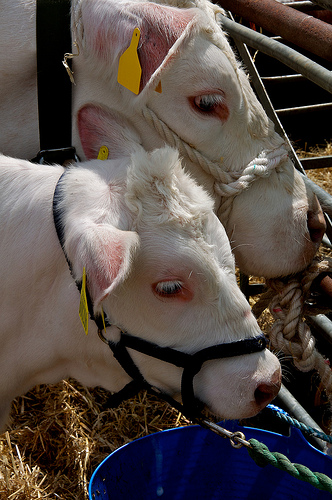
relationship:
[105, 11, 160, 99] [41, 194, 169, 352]
tag in ear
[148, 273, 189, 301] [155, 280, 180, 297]
pink circle around eye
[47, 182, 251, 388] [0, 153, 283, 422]
straps around head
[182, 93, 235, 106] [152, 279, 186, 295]
eyelashes on eye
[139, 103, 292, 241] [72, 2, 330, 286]
rope around head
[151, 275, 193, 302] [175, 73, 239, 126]
ring around eye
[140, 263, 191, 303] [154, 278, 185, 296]
eyelashes on eye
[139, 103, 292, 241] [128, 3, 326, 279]
rope around face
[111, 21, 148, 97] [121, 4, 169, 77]
yelllow tag in ear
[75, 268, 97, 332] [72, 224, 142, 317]
yelllow tag in ear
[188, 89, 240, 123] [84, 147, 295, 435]
eye on side of head